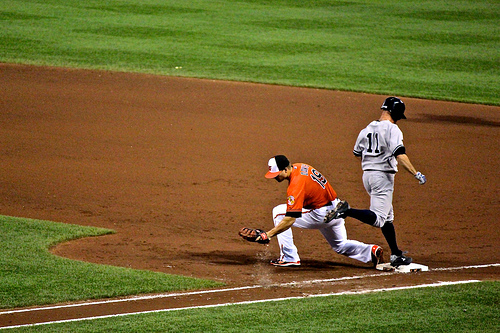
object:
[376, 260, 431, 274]
base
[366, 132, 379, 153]
number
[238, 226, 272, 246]
glove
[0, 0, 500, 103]
grass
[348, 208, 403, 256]
socks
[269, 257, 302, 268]
shoes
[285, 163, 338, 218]
jersey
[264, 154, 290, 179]
cap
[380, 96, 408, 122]
helmet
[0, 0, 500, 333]
field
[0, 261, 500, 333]
lines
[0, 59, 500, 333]
dirt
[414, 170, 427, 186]
gloves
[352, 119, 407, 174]
jersey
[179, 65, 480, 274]
baseball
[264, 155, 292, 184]
head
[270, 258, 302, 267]
cleat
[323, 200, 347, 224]
cleat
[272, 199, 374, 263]
pants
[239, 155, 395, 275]
man